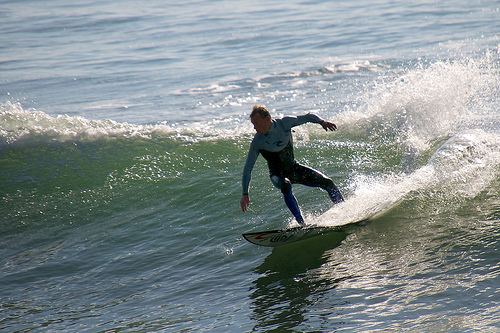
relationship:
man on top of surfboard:
[237, 102, 351, 226] [242, 221, 359, 258]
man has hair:
[237, 102, 351, 226] [248, 107, 275, 124]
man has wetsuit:
[237, 102, 351, 226] [239, 110, 352, 221]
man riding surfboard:
[237, 102, 351, 226] [242, 221, 359, 258]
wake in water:
[314, 163, 426, 232] [3, 3, 499, 332]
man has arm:
[237, 102, 351, 226] [282, 112, 323, 133]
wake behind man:
[314, 163, 426, 232] [237, 102, 351, 226]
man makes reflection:
[237, 102, 351, 226] [250, 271, 337, 332]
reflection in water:
[250, 271, 337, 332] [3, 3, 499, 332]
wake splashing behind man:
[314, 163, 426, 232] [237, 102, 351, 226]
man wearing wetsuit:
[237, 102, 351, 226] [239, 110, 352, 221]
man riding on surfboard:
[237, 102, 351, 226] [242, 221, 359, 258]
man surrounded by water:
[237, 102, 351, 226] [3, 3, 499, 332]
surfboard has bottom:
[242, 221, 359, 258] [250, 230, 320, 250]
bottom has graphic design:
[250, 230, 320, 250] [268, 233, 296, 247]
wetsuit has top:
[239, 110, 352, 221] [239, 112, 322, 185]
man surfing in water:
[237, 102, 351, 226] [3, 3, 499, 332]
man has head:
[237, 102, 351, 226] [249, 107, 271, 138]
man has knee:
[237, 102, 351, 226] [277, 175, 297, 195]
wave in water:
[5, 95, 500, 248] [3, 3, 499, 332]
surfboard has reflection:
[242, 221, 359, 258] [263, 232, 353, 274]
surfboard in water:
[242, 221, 359, 258] [3, 3, 499, 332]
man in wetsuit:
[237, 102, 351, 226] [239, 110, 352, 221]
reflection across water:
[250, 271, 337, 332] [3, 3, 499, 332]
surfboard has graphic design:
[242, 221, 359, 258] [268, 233, 296, 247]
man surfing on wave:
[237, 102, 351, 226] [5, 95, 500, 248]